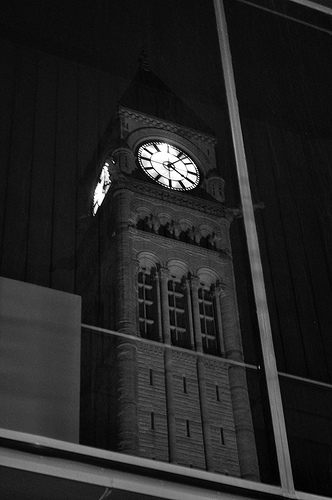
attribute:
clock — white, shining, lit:
[137, 133, 207, 198]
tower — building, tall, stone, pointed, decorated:
[81, 48, 242, 470]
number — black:
[163, 141, 171, 155]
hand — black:
[173, 164, 185, 178]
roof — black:
[118, 55, 217, 135]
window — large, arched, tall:
[136, 243, 163, 346]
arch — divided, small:
[133, 205, 156, 238]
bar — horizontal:
[93, 323, 262, 378]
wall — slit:
[4, 1, 92, 292]